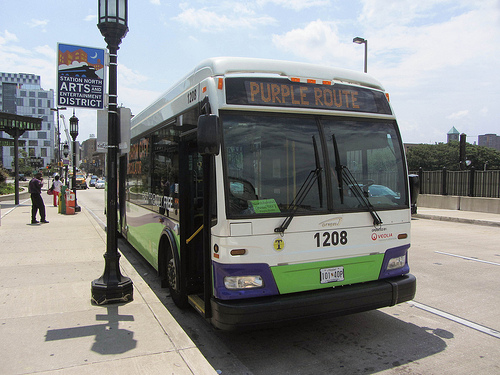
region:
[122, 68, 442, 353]
Bus on the street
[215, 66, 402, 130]
Digital sign on the bus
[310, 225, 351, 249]
Number on front of bus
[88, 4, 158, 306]
Lamp pole on sidewalk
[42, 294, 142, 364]
shadow on the ground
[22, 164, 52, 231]
Man on the sidewalk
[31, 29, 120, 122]
Sign hanging from pole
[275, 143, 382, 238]
Windshield wiper on bus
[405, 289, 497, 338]
White line on road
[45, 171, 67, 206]
Lady on the sidewalk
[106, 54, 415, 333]
a green and white city bus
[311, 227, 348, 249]
1208 written on bus front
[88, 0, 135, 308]
a black street lamp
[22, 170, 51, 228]
man standing on side walk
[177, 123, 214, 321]
door of the bus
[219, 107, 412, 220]
a bus windshield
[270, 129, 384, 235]
two windshield wipers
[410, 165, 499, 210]
guard rail across the street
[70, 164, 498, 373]
large gray street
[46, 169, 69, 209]
a lady with white blouse standing on stree?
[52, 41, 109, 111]
a sign on a lamp post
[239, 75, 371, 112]
the route of a bus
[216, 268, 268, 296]
the right headlight of a bus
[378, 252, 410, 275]
the left headlight of a bus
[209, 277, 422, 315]
the front bumper of a bus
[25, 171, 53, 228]
a man walking on the sidewalk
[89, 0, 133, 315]
a lamp post on the sidewalk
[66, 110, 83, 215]
a lamp post on the sidewalk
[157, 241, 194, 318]
the wheel of a bus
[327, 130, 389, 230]
a windshield wiper on a bus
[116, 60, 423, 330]
A purple green and white city bus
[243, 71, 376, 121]
A bus marquee that says "purple route"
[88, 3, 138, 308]
A lamppost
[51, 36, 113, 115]
A poster advertising arts and entertainment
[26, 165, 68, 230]
Pedestrians on a sidewalk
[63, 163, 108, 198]
Automobile traffic on a city street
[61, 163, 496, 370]
A street in a city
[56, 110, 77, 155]
A construction crane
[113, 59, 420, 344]
A city bus numbered 1208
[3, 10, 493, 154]
A daytime sky with light clouds